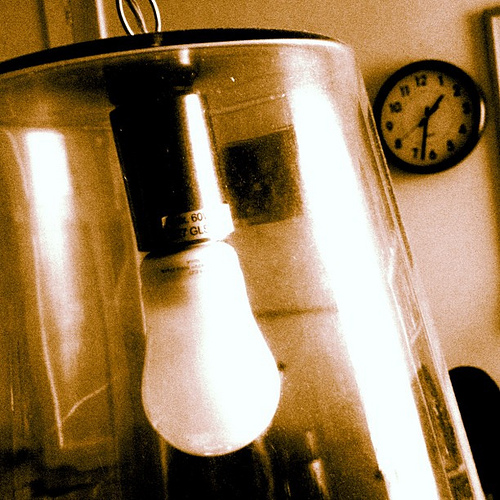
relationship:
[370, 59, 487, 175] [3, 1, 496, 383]
clock on wall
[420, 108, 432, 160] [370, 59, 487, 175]
minute hand on clock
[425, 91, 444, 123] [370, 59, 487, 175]
hour hand on clock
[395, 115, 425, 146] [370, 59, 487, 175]
second hand on clock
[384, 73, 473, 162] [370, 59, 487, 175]
numbers are on clock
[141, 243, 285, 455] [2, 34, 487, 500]
light bulb in container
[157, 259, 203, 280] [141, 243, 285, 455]
label on light bulb